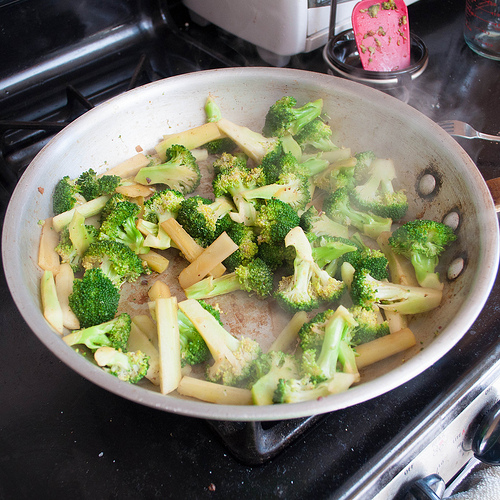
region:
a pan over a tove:
[1, 45, 495, 433]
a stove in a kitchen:
[7, 15, 499, 497]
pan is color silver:
[1, 45, 495, 437]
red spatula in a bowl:
[334, 2, 424, 82]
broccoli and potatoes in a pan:
[33, 81, 438, 395]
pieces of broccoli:
[235, 152, 371, 286]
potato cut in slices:
[156, 213, 237, 288]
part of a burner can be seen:
[198, 422, 320, 479]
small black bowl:
[324, 23, 435, 85]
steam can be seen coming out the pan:
[235, 84, 432, 395]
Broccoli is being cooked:
[279, 230, 343, 306]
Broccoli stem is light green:
[177, 265, 238, 302]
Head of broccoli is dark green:
[240, 256, 275, 298]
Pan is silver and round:
[0, 65, 499, 421]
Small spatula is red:
[345, 0, 415, 69]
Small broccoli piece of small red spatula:
[367, 1, 379, 18]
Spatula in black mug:
[352, 0, 411, 75]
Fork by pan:
[433, 114, 498, 154]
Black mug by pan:
[320, 26, 427, 117]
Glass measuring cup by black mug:
[454, 0, 499, 60]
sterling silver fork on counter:
[438, 120, 498, 146]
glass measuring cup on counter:
[459, 0, 497, 56]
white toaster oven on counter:
[184, 0, 442, 68]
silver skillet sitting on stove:
[1, 71, 498, 419]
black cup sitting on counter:
[324, 15, 427, 105]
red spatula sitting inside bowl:
[354, 0, 411, 71]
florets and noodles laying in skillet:
[36, 107, 444, 384]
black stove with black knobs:
[1, 3, 498, 498]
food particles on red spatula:
[351, 0, 406, 65]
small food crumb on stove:
[206, 481, 217, 495]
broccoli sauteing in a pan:
[234, 186, 358, 284]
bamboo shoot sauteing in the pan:
[147, 282, 187, 397]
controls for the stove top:
[398, 404, 496, 494]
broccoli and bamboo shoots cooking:
[82, 216, 337, 365]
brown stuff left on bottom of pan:
[228, 300, 274, 330]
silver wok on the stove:
[14, 62, 479, 432]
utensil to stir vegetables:
[349, 2, 439, 86]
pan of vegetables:
[91, 289, 309, 341]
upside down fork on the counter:
[431, 105, 496, 158]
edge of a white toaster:
[241, 8, 331, 64]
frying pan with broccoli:
[1, 65, 498, 420]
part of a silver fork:
[436, 117, 498, 144]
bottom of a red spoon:
[350, 0, 414, 71]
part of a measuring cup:
[461, 0, 498, 62]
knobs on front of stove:
[403, 400, 498, 498]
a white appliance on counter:
[179, 0, 419, 64]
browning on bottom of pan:
[211, 289, 286, 341]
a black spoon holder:
[322, 26, 432, 100]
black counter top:
[414, 0, 497, 182]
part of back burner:
[1, 54, 162, 176]